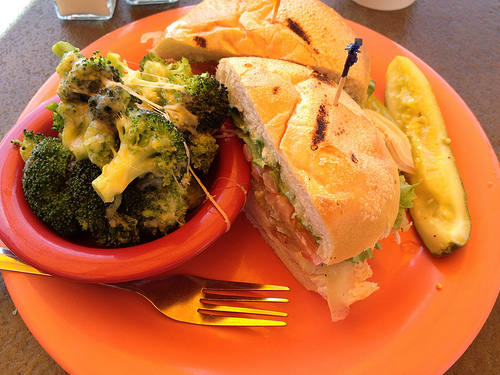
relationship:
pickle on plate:
[385, 57, 486, 253] [452, 91, 499, 159]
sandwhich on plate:
[241, 56, 398, 263] [452, 91, 499, 159]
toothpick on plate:
[334, 38, 364, 108] [452, 91, 499, 159]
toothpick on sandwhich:
[334, 38, 364, 108] [241, 56, 398, 263]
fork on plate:
[196, 272, 304, 347] [452, 91, 499, 159]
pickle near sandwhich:
[385, 57, 486, 253] [241, 56, 398, 263]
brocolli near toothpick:
[66, 58, 196, 205] [334, 38, 364, 108]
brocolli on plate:
[66, 58, 196, 205] [452, 91, 499, 159]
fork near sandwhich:
[196, 272, 304, 347] [241, 56, 398, 263]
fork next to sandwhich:
[196, 272, 304, 347] [241, 56, 398, 263]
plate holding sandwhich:
[452, 91, 499, 159] [241, 56, 398, 263]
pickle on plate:
[382, 57, 471, 260] [10, 15, 480, 372]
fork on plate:
[0, 248, 291, 331] [452, 91, 499, 159]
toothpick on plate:
[318, 24, 372, 114] [10, 15, 480, 372]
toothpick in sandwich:
[318, 24, 372, 114] [203, 30, 396, 294]